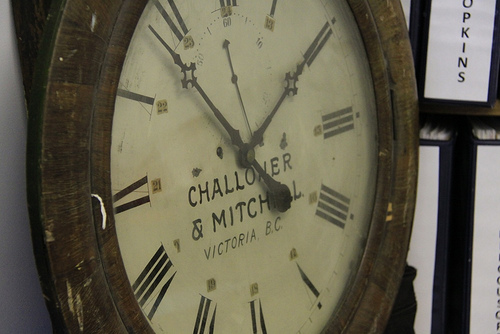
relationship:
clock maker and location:
[178, 152, 312, 232] [195, 211, 293, 280]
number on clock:
[301, 176, 361, 239] [27, 6, 415, 328]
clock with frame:
[10, 0, 422, 333] [329, 25, 441, 260]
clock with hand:
[27, 6, 415, 328] [236, 40, 317, 161]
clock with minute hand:
[27, 6, 415, 328] [142, 21, 293, 214]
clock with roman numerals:
[10, 0, 422, 333] [315, 170, 358, 245]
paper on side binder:
[413, 5, 497, 96] [410, 15, 491, 127]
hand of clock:
[248, 44, 319, 149] [27, 6, 415, 328]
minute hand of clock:
[178, 57, 267, 164] [27, 6, 415, 328]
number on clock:
[288, 260, 325, 303] [27, 6, 415, 328]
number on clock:
[315, 101, 364, 143] [27, 6, 415, 328]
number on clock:
[109, 172, 150, 216] [27, 6, 415, 328]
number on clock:
[113, 81, 161, 113] [27, 6, 415, 328]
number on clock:
[129, 234, 179, 316] [27, 6, 415, 328]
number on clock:
[185, 291, 225, 333] [27, 6, 415, 328]